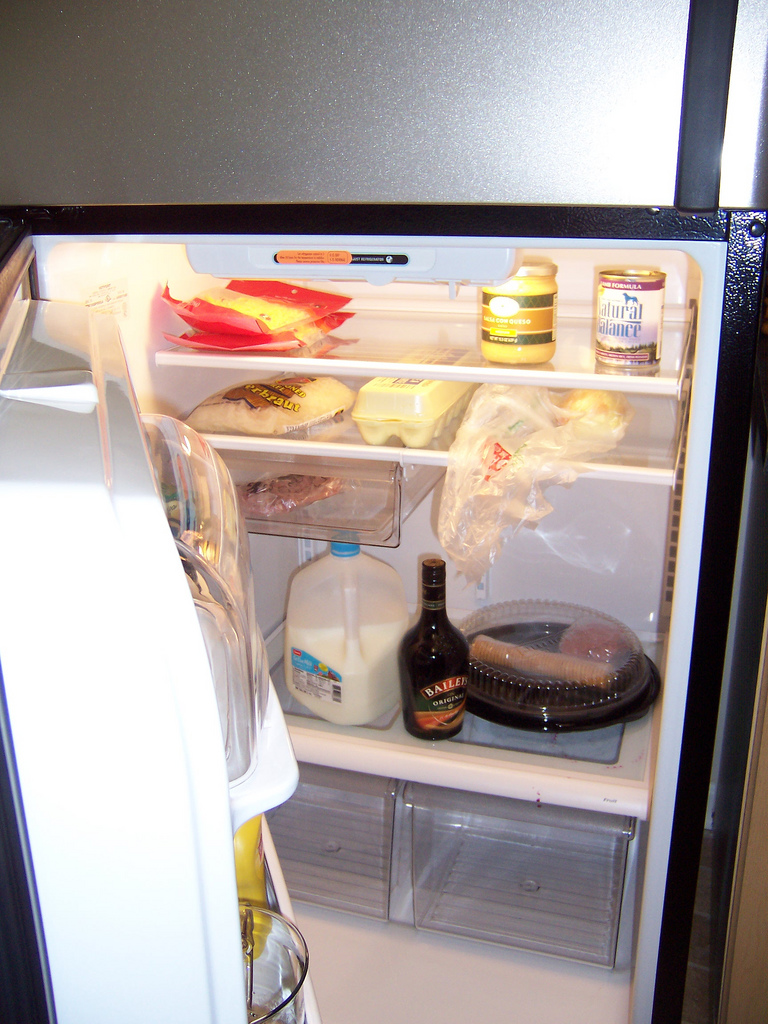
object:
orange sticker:
[277, 250, 352, 264]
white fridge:
[0, 205, 768, 1024]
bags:
[160, 279, 357, 351]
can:
[595, 268, 667, 369]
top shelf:
[155, 348, 678, 401]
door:
[0, 0, 768, 1023]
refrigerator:
[0, 235, 318, 1024]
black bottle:
[398, 559, 469, 742]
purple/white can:
[595, 270, 667, 369]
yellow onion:
[564, 389, 630, 437]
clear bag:
[437, 383, 637, 590]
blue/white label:
[291, 646, 343, 704]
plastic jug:
[284, 531, 411, 727]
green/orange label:
[481, 292, 557, 345]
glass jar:
[480, 261, 558, 365]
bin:
[386, 788, 638, 969]